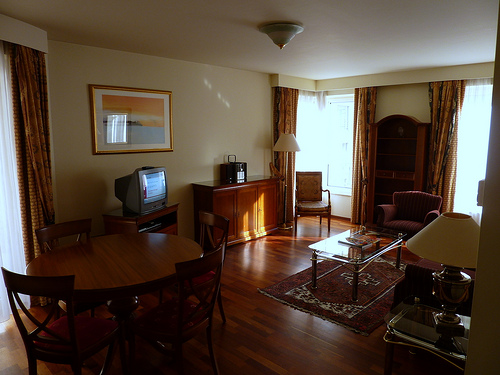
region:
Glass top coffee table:
[311, 221, 409, 306]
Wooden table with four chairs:
[7, 212, 244, 352]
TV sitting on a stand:
[109, 165, 186, 219]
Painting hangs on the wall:
[81, 81, 192, 154]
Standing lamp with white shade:
[269, 131, 307, 243]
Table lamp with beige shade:
[404, 211, 490, 372]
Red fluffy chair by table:
[372, 184, 442, 251]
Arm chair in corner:
[291, 165, 339, 241]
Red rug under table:
[267, 225, 425, 347]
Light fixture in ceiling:
[253, 13, 313, 58]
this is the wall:
[199, 86, 247, 156]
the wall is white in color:
[201, 75, 263, 134]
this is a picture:
[86, 75, 193, 162]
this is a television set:
[115, 162, 170, 212]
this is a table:
[38, 240, 181, 272]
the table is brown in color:
[108, 244, 137, 263]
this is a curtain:
[435, 89, 447, 190]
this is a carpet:
[320, 274, 339, 309]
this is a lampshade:
[269, 133, 312, 224]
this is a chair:
[289, 168, 341, 232]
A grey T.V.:
[106, 163, 171, 218]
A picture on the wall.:
[80, 76, 180, 160]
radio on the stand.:
[214, 148, 252, 180]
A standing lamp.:
[267, 124, 304, 234]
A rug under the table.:
[266, 234, 378, 338]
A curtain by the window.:
[346, 85, 371, 227]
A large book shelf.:
[359, 105, 430, 227]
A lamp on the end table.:
[403, 209, 487, 342]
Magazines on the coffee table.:
[335, 228, 384, 255]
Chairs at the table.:
[2, 246, 227, 373]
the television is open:
[92, 130, 212, 231]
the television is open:
[102, 142, 256, 306]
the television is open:
[101, 143, 162, 198]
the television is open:
[110, 138, 184, 210]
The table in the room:
[24, 227, 216, 326]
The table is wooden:
[28, 229, 252, 325]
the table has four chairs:
[5, 223, 250, 355]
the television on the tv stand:
[116, 163, 176, 228]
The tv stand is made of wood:
[103, 202, 204, 238]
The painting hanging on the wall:
[81, 78, 181, 163]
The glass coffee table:
[305, 220, 407, 307]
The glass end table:
[357, 283, 481, 360]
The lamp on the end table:
[397, 201, 483, 336]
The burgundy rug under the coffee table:
[248, 244, 400, 338]